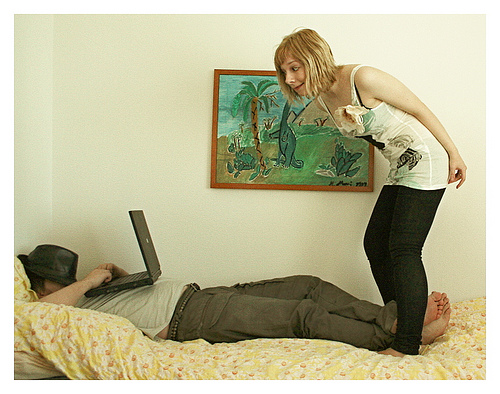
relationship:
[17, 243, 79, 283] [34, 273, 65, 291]
hat covering face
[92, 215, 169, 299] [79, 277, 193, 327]
laptop resting on man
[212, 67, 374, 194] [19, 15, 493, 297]
painting hanging on wall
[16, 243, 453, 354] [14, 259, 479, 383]
man lying on bed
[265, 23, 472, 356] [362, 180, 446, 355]
woman wearing black jeans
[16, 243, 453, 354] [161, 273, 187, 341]
man wearing belt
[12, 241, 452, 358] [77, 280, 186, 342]
man wearing shirt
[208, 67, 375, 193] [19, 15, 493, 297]
painting on wall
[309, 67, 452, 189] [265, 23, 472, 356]
shirt on woman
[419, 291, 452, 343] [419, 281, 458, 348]
feet on feet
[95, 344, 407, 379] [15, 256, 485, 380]
print on bedspread